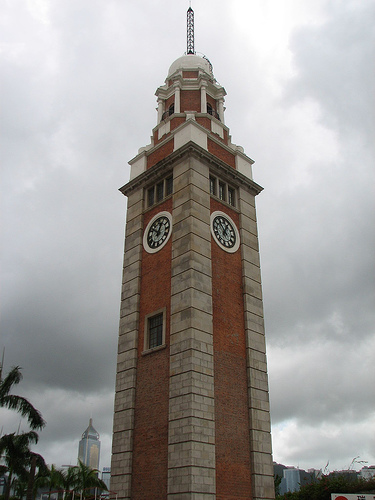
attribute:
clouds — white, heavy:
[3, 4, 373, 462]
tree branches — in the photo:
[0, 346, 106, 499]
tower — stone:
[130, 41, 272, 291]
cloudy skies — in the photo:
[265, 28, 319, 156]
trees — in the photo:
[64, 462, 105, 492]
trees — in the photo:
[0, 428, 45, 498]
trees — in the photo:
[34, 463, 66, 498]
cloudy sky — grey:
[4, 4, 373, 470]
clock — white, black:
[140, 207, 174, 255]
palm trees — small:
[9, 385, 114, 496]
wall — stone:
[147, 290, 243, 374]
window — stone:
[141, 310, 173, 353]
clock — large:
[136, 208, 243, 255]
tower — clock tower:
[103, 0, 265, 317]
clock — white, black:
[213, 213, 236, 251]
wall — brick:
[210, 197, 252, 499]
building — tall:
[125, 45, 262, 262]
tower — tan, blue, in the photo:
[99, 3, 288, 491]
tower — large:
[108, 64, 296, 308]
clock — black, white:
[211, 210, 237, 251]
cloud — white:
[266, 334, 374, 424]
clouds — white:
[236, 36, 353, 143]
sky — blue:
[0, 1, 373, 480]